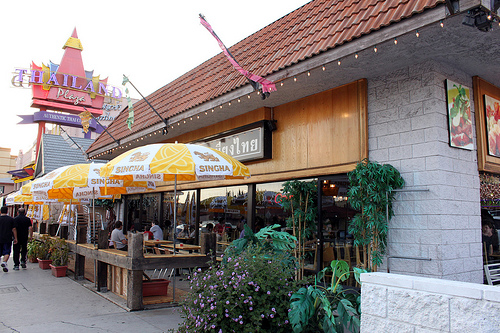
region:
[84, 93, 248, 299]
the umbrella is yellow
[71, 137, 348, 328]
the umbrella is yellow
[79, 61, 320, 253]
the umbrella is yellow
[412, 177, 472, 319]
A brick wall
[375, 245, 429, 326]
A brick wall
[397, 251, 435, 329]
A brick wall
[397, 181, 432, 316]
A brick wall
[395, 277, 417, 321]
A brick wall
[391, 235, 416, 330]
A brick wall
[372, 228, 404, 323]
A brick wall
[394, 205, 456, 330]
A brick wall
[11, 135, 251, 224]
a row of orange and white umbrellas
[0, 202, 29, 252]
two people walking on a side walk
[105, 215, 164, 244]
three people sitting at a table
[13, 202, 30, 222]
a man going bald on his head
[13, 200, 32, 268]
a man wearing black clothes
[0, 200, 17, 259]
a man wearing black shorts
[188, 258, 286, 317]
a bush with purple flowers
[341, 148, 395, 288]
a tall green plant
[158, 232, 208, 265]
a wooden table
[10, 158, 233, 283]
a outdoor resturant